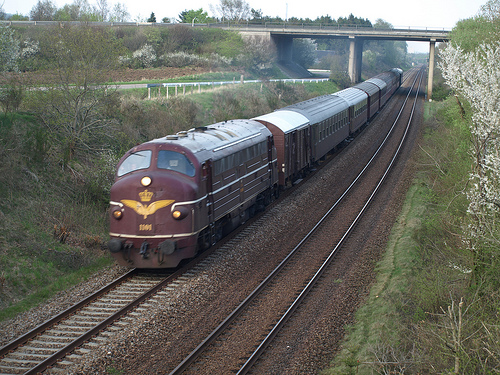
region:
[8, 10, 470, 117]
A bridge in the background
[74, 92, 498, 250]
The train is brown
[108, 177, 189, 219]
A yellow bird on the train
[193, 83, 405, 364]
Train tracks right here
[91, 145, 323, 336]
A train is on these tracks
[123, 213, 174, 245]
"1305" are the numbers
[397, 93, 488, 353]
Grass besides the track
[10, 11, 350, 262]
Trees by the train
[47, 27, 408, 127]
White gate in the grass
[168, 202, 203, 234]
Yellow lights by the bird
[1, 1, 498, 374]
train traveling out of bridge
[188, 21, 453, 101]
concrete bridge over railraod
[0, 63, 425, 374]
maroon train on tracks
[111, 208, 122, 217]
left yellow headlight on train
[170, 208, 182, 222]
right yellow headlight on train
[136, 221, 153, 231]
train number on engine car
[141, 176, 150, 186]
white headlight on engine car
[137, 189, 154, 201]
golden crown on engine car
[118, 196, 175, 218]
golden wings on engine car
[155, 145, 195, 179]
right front window on engine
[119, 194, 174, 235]
a paintedb golden eagle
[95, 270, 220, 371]
rocks between rail road tracks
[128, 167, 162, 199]
a round circular white light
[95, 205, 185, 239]
two head lights on a train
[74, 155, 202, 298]
maroon and gold front of train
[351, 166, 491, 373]
green and brown shrubbery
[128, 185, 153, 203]
a painted golden crown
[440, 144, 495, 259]
white blossoms ona tree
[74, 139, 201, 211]
two front windows on a train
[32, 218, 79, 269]
shrubbery in the grass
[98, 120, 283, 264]
A red train engine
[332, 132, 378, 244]
a metal rail road track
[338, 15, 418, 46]
A bridge over the rail road.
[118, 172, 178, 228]
Three lights on front train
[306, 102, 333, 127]
A train car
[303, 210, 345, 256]
small rocks between rail tracks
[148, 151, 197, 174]
Engineers observation window.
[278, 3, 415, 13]
A background sky is white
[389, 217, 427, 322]
grass on the side of the rail road tracks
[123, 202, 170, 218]
A bird design the front of the engine.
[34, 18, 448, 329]
Train traveling through rural area.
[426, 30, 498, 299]
White blossoms on a tree.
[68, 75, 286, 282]
A burgundy colored train engine.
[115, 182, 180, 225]
A gold design on engine.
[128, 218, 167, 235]
The number 1501 on train engine.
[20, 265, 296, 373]
Two sets of train tracks.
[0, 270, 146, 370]
Cross ties on left tracks.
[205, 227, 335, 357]
Cross ties on right tracks.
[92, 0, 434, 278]
Train passing under a bridge.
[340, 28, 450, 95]
Concrete supports for overhead bridge.